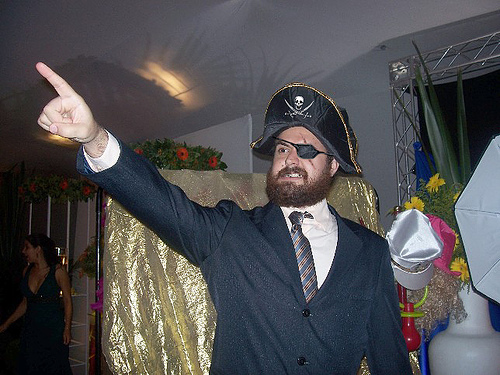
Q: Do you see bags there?
A: No, there are no bags.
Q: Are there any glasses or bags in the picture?
A: No, there are no bags or glasses.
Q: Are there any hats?
A: Yes, there is a hat.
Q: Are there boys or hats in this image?
A: Yes, there is a hat.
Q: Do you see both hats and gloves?
A: No, there is a hat but no gloves.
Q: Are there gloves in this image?
A: No, there are no gloves.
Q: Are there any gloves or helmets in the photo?
A: No, there are no gloves or helmets.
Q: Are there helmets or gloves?
A: No, there are no gloves or helmets.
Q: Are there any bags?
A: No, there are no bags.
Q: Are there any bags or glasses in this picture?
A: No, there are no bags or glasses.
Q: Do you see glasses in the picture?
A: No, there are no glasses.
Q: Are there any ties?
A: Yes, there is a tie.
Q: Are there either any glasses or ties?
A: Yes, there is a tie.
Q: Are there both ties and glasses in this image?
A: No, there is a tie but no glasses.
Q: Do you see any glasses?
A: No, there are no glasses.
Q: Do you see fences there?
A: No, there are no fences.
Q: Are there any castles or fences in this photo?
A: No, there are no fences or castles.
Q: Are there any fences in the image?
A: No, there are no fences.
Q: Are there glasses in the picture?
A: No, there are no glasses.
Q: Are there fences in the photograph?
A: No, there are no fences.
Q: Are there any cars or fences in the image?
A: No, there are no fences or cars.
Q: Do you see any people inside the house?
A: Yes, there is a person inside the house.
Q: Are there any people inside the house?
A: Yes, there is a person inside the house.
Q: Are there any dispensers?
A: No, there are no dispensers.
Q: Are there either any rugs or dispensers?
A: No, there are no dispensers or rugs.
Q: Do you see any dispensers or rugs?
A: No, there are no dispensers or rugs.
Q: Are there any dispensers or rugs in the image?
A: No, there are no dispensers or rugs.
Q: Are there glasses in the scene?
A: No, there are no glasses.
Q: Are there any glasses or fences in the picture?
A: No, there are no glasses or fences.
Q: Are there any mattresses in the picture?
A: No, there are no mattresses.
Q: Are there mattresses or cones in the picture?
A: No, there are no mattresses or cones.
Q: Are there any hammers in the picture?
A: No, there are no hammers.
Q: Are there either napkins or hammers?
A: No, there are no hammers or napkins.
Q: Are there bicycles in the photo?
A: No, there are no bicycles.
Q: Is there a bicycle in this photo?
A: No, there are no bicycles.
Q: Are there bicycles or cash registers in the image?
A: No, there are no bicycles or cash registers.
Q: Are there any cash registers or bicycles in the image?
A: No, there are no bicycles or cash registers.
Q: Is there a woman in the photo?
A: Yes, there is a woman.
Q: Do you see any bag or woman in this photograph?
A: Yes, there is a woman.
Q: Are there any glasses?
A: No, there are no glasses.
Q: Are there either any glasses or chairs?
A: No, there are no glasses or chairs.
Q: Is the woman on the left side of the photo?
A: Yes, the woman is on the left of the image.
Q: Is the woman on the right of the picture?
A: No, the woman is on the left of the image.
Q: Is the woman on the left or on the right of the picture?
A: The woman is on the left of the image.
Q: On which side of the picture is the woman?
A: The woman is on the left of the image.